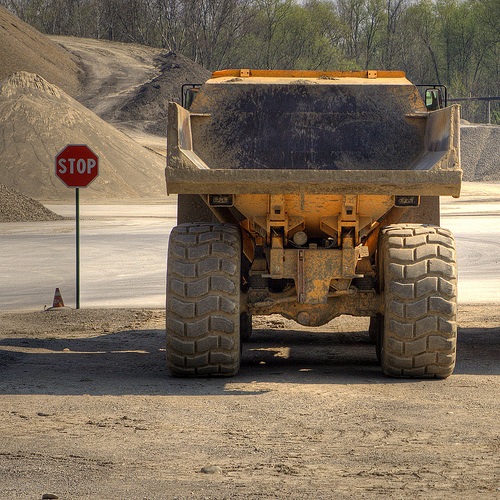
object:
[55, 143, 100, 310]
whole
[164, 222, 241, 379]
rear wheel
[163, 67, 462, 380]
tractor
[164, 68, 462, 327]
yellow metal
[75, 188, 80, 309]
pole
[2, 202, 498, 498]
ground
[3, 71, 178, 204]
gravel pile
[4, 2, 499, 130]
trees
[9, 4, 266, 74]
dead trees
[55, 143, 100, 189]
sign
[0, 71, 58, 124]
gravel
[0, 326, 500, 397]
shadow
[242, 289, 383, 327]
rear axle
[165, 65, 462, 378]
machine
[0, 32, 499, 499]
field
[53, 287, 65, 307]
cone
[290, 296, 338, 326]
metal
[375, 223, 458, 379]
right wheel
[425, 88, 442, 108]
mirror